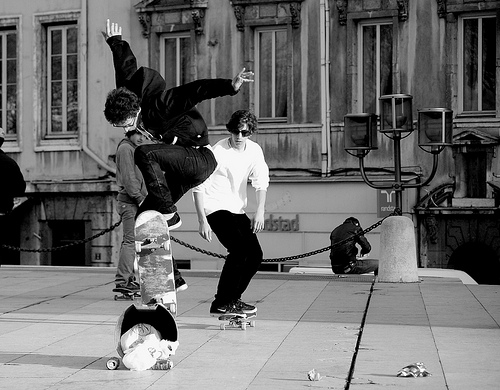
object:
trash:
[290, 359, 338, 388]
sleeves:
[245, 160, 274, 196]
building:
[3, 0, 500, 271]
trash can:
[115, 302, 180, 371]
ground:
[257, 274, 499, 336]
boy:
[189, 108, 272, 320]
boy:
[99, 17, 257, 302]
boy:
[110, 129, 150, 301]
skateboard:
[216, 306, 257, 332]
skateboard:
[128, 207, 179, 322]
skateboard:
[109, 270, 136, 301]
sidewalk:
[0, 265, 500, 390]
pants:
[205, 209, 267, 314]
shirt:
[189, 139, 273, 221]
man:
[322, 215, 378, 279]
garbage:
[102, 292, 185, 377]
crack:
[343, 280, 375, 390]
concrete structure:
[373, 208, 425, 287]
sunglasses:
[226, 125, 256, 138]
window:
[252, 22, 295, 124]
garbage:
[391, 360, 434, 381]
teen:
[90, 13, 274, 339]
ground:
[0, 266, 500, 390]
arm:
[97, 17, 141, 89]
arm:
[163, 64, 256, 106]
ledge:
[289, 263, 500, 290]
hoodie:
[128, 61, 168, 101]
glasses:
[227, 127, 252, 138]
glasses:
[105, 116, 138, 131]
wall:
[269, 181, 377, 217]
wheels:
[134, 240, 143, 253]